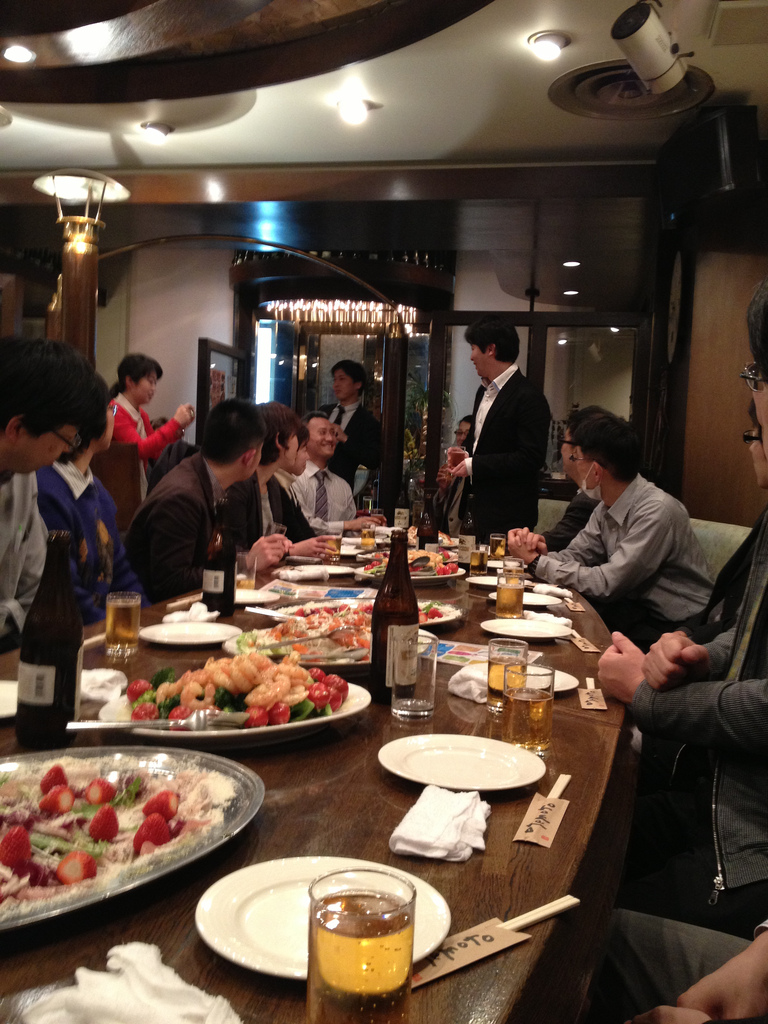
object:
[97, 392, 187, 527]
sweater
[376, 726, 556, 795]
plate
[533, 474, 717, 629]
shirt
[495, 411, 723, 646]
man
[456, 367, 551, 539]
jacket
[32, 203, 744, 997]
establishment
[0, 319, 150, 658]
people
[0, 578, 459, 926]
meals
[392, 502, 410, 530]
glass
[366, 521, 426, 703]
wine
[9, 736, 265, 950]
tray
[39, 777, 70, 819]
strawberry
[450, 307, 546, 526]
man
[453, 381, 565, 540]
suit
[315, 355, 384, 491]
man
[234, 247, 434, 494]
door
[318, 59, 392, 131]
lights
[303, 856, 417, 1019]
glass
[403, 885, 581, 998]
chopsticks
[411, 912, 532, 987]
paper holder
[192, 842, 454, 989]
plate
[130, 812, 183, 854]
radishes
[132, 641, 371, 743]
shrimp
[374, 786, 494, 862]
towel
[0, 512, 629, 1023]
table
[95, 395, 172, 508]
shirt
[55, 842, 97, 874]
radishes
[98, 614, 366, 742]
tray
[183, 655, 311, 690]
shrimp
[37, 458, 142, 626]
shirt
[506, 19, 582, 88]
lights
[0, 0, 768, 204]
ceiling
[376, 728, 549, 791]
plate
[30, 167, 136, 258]
light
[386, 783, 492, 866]
napkins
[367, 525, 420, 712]
bottle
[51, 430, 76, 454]
side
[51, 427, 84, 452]
eyeglasses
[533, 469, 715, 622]
shirt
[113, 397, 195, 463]
arm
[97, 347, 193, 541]
woman